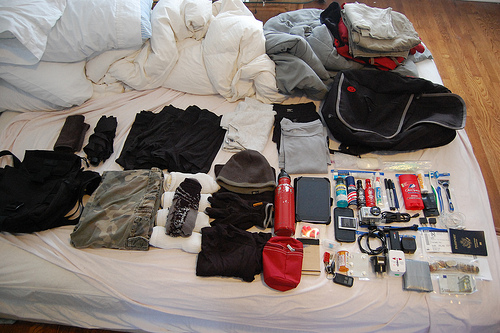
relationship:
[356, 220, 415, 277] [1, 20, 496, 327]
adapter on mattress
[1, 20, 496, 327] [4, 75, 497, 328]
mattress has white sheet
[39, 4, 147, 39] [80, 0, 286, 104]
pillows on white sheet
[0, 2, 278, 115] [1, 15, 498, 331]
bedding wad on bed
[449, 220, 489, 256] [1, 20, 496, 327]
passport on mattress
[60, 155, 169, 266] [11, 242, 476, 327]
army pants on mattress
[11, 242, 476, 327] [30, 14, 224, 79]
mattress with white sheet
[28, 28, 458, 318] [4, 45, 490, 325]
ink pens on mattress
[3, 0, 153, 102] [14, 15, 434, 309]
pillows on bed